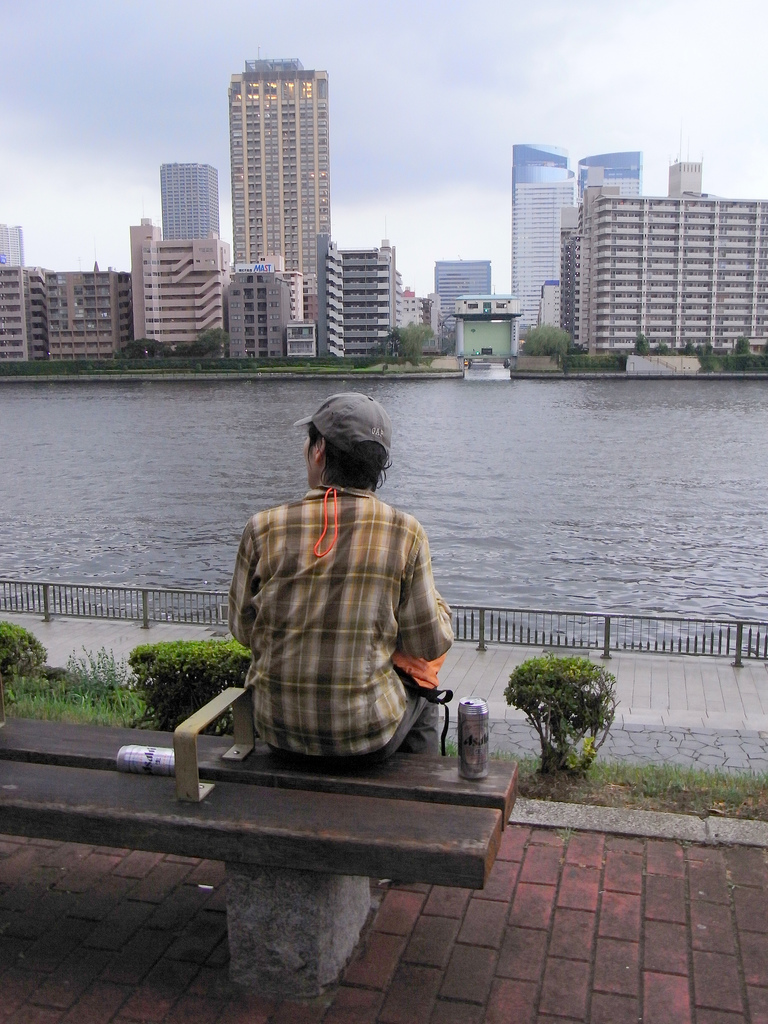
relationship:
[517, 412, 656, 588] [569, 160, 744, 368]
water in front of building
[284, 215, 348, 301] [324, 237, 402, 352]
wall on building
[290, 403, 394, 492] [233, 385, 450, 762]
head of a person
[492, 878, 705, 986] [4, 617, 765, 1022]
lines on ground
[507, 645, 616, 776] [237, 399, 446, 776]
bush in front of person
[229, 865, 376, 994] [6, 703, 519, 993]
part of bench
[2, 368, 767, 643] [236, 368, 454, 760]
water in front of man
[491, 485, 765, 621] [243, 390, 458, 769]
waves in front of person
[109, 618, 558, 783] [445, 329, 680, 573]
building near water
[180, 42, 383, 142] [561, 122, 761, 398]
top of building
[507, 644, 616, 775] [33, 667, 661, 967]
bush near a bench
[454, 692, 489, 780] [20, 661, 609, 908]
beer on a bench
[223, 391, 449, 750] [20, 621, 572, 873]
man on a bench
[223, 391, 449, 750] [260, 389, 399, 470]
man in cap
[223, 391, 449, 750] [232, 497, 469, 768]
man in shirt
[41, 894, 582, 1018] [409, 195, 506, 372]
walkway of brick pavers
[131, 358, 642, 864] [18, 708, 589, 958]
man on a bench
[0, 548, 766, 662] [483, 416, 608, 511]
fence by water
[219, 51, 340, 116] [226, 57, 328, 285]
wall on building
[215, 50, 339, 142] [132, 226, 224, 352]
wall on building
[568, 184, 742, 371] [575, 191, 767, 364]
wall on building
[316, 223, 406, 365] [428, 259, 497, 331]
wall on building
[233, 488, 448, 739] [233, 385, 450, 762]
back of person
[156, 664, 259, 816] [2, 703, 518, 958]
bar on bench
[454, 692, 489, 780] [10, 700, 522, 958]
beer on bench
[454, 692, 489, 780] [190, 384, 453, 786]
beer by man